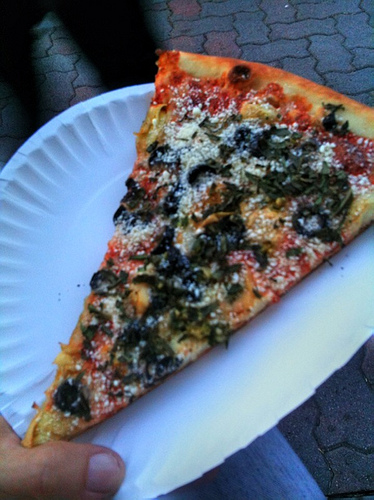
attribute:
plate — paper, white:
[14, 97, 108, 230]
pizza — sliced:
[70, 69, 360, 344]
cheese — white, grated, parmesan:
[169, 98, 237, 163]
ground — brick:
[186, 17, 348, 72]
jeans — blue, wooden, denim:
[258, 434, 316, 495]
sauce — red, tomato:
[204, 64, 229, 100]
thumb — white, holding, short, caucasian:
[15, 419, 171, 491]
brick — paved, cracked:
[294, 20, 367, 68]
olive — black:
[81, 274, 151, 309]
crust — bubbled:
[198, 53, 333, 119]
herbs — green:
[203, 129, 356, 263]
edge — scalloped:
[218, 397, 301, 444]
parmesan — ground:
[177, 140, 229, 195]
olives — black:
[122, 178, 181, 224]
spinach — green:
[211, 133, 333, 209]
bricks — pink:
[246, 14, 373, 75]